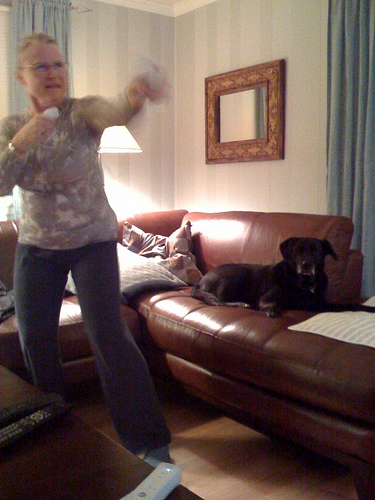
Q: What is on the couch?
A: A dog.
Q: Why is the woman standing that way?
A: She is playing Wii.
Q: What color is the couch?
A: Brown.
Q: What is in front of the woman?
A: Remote controls and a Wii remote.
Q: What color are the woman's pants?
A: Grey.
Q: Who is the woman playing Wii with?
A: Nobody.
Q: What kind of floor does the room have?
A: Hardwood.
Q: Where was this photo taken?
A: In a living room.